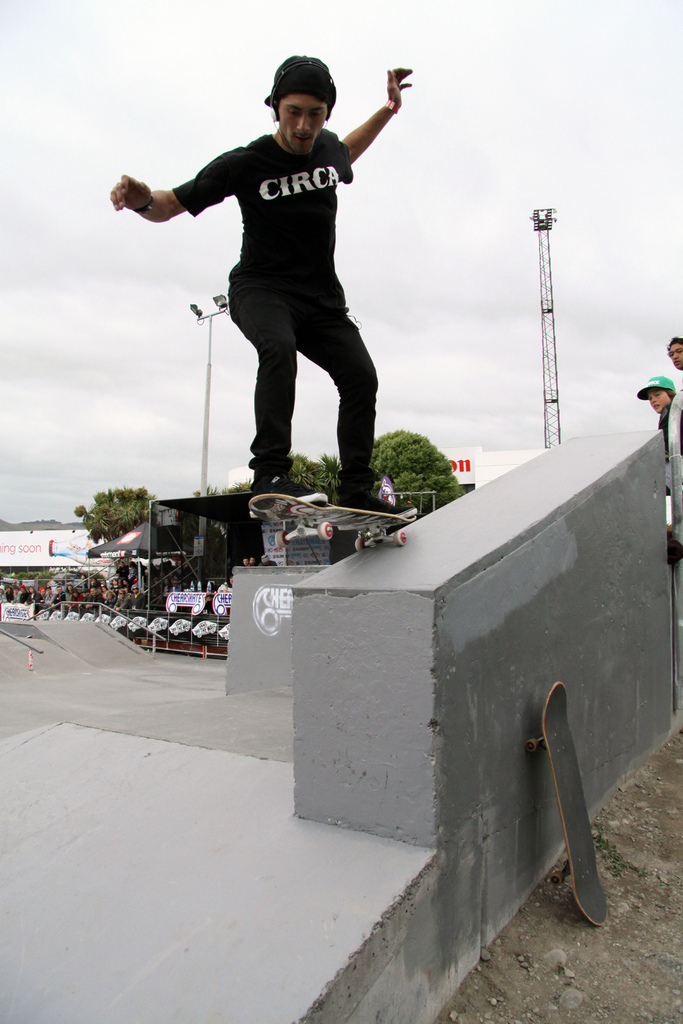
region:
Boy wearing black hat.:
[269, 57, 349, 122]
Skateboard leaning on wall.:
[526, 676, 614, 938]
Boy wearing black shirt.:
[171, 134, 363, 306]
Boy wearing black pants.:
[227, 294, 375, 497]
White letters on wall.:
[255, 581, 297, 644]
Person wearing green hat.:
[640, 374, 681, 407]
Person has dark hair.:
[665, 335, 679, 348]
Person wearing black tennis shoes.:
[246, 460, 426, 519]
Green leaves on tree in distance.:
[78, 494, 149, 537]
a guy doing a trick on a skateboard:
[96, 42, 469, 528]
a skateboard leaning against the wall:
[530, 671, 630, 934]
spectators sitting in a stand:
[7, 532, 167, 629]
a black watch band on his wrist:
[135, 180, 167, 228]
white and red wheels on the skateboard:
[256, 524, 416, 551]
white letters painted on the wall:
[247, 578, 315, 641]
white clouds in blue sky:
[80, 266, 117, 311]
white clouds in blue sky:
[71, 353, 126, 386]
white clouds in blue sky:
[106, 413, 167, 459]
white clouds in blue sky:
[414, 301, 501, 386]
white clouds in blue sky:
[543, 93, 660, 166]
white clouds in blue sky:
[124, 43, 194, 92]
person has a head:
[645, 377, 672, 412]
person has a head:
[665, 337, 681, 363]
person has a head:
[129, 583, 138, 595]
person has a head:
[89, 584, 96, 594]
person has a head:
[62, 583, 71, 589]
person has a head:
[68, 589, 76, 598]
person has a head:
[39, 589, 49, 597]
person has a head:
[21, 584, 32, 592]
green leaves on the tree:
[396, 454, 425, 477]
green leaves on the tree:
[403, 450, 424, 465]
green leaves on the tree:
[378, 440, 403, 459]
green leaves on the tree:
[310, 457, 329, 476]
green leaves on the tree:
[288, 455, 307, 474]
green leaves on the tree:
[132, 471, 155, 510]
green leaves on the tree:
[93, 500, 110, 517]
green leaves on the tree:
[81, 510, 118, 537]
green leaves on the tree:
[89, 485, 153, 559]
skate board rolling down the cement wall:
[247, 490, 424, 548]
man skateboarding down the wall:
[110, 53, 415, 555]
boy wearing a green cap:
[636, 373, 680, 415]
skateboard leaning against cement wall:
[522, 675, 612, 929]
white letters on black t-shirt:
[257, 162, 339, 200]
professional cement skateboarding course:
[0, 597, 314, 1021]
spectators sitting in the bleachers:
[2, 558, 179, 603]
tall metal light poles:
[187, 291, 230, 494]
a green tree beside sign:
[70, 486, 150, 543]